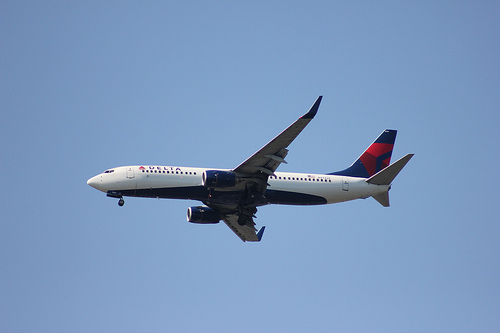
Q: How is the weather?
A: It is clear.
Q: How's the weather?
A: It is clear.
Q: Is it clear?
A: Yes, it is clear.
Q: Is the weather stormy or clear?
A: It is clear.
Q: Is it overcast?
A: No, it is clear.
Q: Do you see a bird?
A: No, there are no birds.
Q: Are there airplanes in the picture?
A: Yes, there is an airplane.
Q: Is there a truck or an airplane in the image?
A: Yes, there is an airplane.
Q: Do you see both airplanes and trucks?
A: No, there is an airplane but no trucks.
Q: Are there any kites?
A: No, there are no kites.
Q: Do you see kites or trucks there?
A: No, there are no kites or trucks.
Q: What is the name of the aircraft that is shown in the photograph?
A: The aircraft is an airplane.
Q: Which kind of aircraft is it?
A: The aircraft is an airplane.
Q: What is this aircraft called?
A: This is an airplane.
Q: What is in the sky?
A: The airplane is in the sky.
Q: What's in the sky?
A: The airplane is in the sky.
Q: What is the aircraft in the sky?
A: The aircraft is an airplane.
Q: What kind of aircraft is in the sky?
A: The aircraft is an airplane.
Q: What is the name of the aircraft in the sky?
A: The aircraft is an airplane.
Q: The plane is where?
A: The plane is in the sky.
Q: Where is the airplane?
A: The plane is in the sky.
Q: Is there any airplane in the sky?
A: Yes, there is an airplane in the sky.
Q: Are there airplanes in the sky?
A: Yes, there is an airplane in the sky.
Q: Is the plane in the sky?
A: Yes, the plane is in the sky.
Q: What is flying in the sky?
A: The plane is flying in the sky.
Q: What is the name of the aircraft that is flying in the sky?
A: The aircraft is an airplane.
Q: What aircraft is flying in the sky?
A: The aircraft is an airplane.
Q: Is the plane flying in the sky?
A: Yes, the plane is flying in the sky.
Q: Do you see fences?
A: No, there are no fences.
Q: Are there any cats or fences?
A: No, there are no fences or cats.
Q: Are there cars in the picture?
A: No, there are no cars.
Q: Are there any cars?
A: No, there are no cars.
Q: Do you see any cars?
A: No, there are no cars.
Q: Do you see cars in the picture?
A: No, there are no cars.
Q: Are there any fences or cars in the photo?
A: No, there are no cars or fences.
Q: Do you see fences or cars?
A: No, there are no cars or fences.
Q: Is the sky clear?
A: Yes, the sky is clear.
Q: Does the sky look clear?
A: Yes, the sky is clear.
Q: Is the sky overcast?
A: No, the sky is clear.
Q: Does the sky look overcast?
A: No, the sky is clear.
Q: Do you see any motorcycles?
A: No, there are no motorcycles.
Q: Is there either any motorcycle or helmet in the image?
A: No, there are no motorcycles or helmets.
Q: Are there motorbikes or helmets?
A: No, there are no motorbikes or helmets.